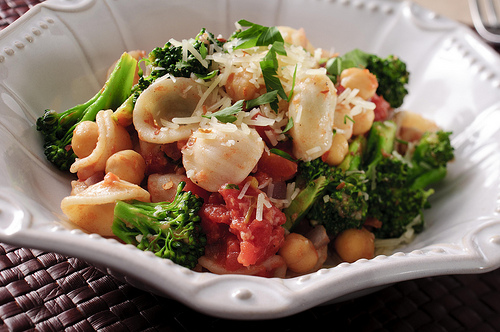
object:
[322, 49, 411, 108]
broccoli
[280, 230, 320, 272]
peas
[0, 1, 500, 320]
bowl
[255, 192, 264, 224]
cheese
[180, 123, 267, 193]
piece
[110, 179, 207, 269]
broccoli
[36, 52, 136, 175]
broccoli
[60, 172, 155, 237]
food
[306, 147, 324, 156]
cheese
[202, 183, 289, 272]
tomatoes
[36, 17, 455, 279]
salad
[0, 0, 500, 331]
table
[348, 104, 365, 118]
flakes